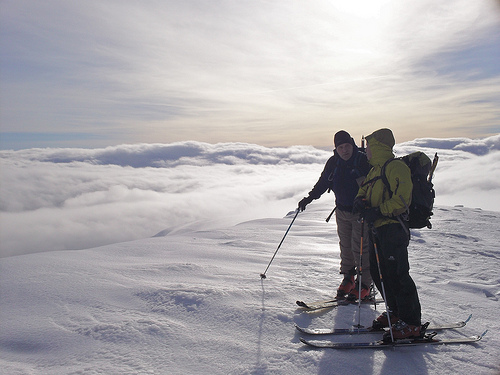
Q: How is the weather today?
A: It is cloudy.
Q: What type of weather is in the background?
A: It is cloudy.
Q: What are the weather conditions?
A: It is cloudy.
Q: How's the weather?
A: It is cloudy.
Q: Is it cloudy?
A: Yes, it is cloudy.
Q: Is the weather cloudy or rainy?
A: It is cloudy.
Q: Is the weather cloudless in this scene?
A: No, it is cloudy.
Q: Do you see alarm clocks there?
A: No, there are no alarm clocks.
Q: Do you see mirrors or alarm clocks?
A: No, there are no alarm clocks or mirrors.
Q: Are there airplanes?
A: No, there are no airplanes.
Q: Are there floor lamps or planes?
A: No, there are no planes or floor lamps.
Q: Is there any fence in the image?
A: No, there are no fences.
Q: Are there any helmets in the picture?
A: No, there are no helmets.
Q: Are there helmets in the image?
A: No, there are no helmets.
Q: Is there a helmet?
A: No, there are no helmets.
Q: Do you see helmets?
A: No, there are no helmets.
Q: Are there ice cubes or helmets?
A: No, there are no helmets or ice cubes.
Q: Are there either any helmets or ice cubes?
A: No, there are no helmets or ice cubes.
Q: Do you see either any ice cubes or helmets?
A: No, there are no helmets or ice cubes.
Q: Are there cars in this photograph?
A: No, there are no cars.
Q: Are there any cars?
A: No, there are no cars.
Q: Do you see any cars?
A: No, there are no cars.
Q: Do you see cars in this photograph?
A: No, there are no cars.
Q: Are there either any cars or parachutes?
A: No, there are no cars or parachutes.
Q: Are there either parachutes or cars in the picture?
A: No, there are no cars or parachutes.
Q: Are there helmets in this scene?
A: No, there are no helmets.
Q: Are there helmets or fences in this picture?
A: No, there are no helmets or fences.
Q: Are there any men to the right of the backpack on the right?
A: No, the man is to the left of the backpack.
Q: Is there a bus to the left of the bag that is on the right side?
A: No, there is a man to the left of the backpack.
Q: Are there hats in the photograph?
A: Yes, there is a hat.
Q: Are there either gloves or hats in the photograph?
A: Yes, there is a hat.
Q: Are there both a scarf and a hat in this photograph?
A: No, there is a hat but no scarves.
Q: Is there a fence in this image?
A: No, there are no fences.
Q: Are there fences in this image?
A: No, there are no fences.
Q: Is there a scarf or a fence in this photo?
A: No, there are no fences or scarves.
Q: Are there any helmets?
A: No, there are no helmets.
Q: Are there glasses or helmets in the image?
A: No, there are no helmets or glasses.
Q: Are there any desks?
A: No, there are no desks.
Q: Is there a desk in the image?
A: No, there are no desks.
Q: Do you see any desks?
A: No, there are no desks.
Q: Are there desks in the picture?
A: No, there are no desks.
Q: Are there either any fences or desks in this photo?
A: No, there are no desks or fences.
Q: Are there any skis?
A: Yes, there are skis.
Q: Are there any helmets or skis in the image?
A: Yes, there are skis.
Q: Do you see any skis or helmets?
A: Yes, there are skis.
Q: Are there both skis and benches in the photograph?
A: No, there are skis but no benches.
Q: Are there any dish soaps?
A: No, there are no dish soaps.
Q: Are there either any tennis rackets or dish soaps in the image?
A: No, there are no dish soaps or tennis rackets.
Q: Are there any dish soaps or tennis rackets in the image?
A: No, there are no dish soaps or tennis rackets.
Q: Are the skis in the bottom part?
A: Yes, the skis are in the bottom of the image.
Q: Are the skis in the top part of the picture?
A: No, the skis are in the bottom of the image.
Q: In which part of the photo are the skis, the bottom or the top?
A: The skis are in the bottom of the image.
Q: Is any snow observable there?
A: Yes, there is snow.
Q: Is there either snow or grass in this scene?
A: Yes, there is snow.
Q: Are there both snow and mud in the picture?
A: No, there is snow but no mud.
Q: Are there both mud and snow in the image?
A: No, there is snow but no mud.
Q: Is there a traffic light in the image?
A: No, there are no traffic lights.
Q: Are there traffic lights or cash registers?
A: No, there are no traffic lights or cash registers.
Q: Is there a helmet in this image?
A: No, there are no helmets.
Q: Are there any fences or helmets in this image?
A: No, there are no helmets or fences.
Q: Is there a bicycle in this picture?
A: No, there are no bicycles.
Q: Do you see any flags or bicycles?
A: No, there are no bicycles or flags.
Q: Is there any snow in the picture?
A: Yes, there is snow.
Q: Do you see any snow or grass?
A: Yes, there is snow.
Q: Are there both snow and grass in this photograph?
A: No, there is snow but no grass.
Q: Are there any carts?
A: No, there are no carts.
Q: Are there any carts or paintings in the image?
A: No, there are no carts or paintings.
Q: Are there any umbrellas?
A: No, there are no umbrellas.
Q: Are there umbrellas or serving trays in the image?
A: No, there are no umbrellas or serving trays.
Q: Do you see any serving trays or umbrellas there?
A: No, there are no umbrellas or serving trays.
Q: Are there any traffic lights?
A: No, there are no traffic lights.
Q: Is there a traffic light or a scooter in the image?
A: No, there are no traffic lights or scooters.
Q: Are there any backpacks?
A: Yes, there is a backpack.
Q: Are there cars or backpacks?
A: Yes, there is a backpack.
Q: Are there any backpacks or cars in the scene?
A: Yes, there is a backpack.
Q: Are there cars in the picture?
A: No, there are no cars.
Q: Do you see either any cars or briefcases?
A: No, there are no cars or briefcases.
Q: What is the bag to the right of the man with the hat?
A: The bag is a backpack.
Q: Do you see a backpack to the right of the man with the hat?
A: Yes, there is a backpack to the right of the man.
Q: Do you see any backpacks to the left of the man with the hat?
A: No, the backpack is to the right of the man.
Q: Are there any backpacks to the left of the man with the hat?
A: No, the backpack is to the right of the man.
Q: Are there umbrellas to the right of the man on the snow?
A: No, there is a backpack to the right of the man.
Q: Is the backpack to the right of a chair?
A: No, the backpack is to the right of the man.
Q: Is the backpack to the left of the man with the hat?
A: No, the backpack is to the right of the man.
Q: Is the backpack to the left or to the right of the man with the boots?
A: The backpack is to the right of the man.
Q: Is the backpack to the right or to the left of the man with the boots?
A: The backpack is to the right of the man.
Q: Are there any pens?
A: No, there are no pens.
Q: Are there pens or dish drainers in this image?
A: No, there are no pens or dish drainers.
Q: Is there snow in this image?
A: Yes, there is snow.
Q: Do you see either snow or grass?
A: Yes, there is snow.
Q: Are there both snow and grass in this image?
A: No, there is snow but no grass.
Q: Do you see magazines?
A: No, there are no magazines.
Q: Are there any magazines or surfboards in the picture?
A: No, there are no magazines or surfboards.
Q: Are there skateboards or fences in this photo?
A: No, there are no fences or skateboards.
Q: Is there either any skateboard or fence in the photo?
A: No, there are no fences or skateboards.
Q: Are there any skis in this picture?
A: Yes, there are skis.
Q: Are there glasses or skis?
A: Yes, there are skis.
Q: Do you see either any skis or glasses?
A: Yes, there are skis.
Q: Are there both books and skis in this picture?
A: No, there are skis but no books.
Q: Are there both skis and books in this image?
A: No, there are skis but no books.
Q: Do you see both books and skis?
A: No, there are skis but no books.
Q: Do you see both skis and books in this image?
A: No, there are skis but no books.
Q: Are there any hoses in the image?
A: No, there are no hoses.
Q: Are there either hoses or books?
A: No, there are no hoses or books.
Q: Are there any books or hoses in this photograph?
A: No, there are no hoses or books.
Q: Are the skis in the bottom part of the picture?
A: Yes, the skis are in the bottom of the image.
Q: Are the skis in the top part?
A: No, the skis are in the bottom of the image.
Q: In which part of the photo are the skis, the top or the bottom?
A: The skis are in the bottom of the image.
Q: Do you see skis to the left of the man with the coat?
A: Yes, there are skis to the left of the man.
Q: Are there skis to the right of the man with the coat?
A: No, the skis are to the left of the man.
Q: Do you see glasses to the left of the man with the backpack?
A: No, there are skis to the left of the man.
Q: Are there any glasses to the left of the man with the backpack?
A: No, there are skis to the left of the man.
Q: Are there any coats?
A: Yes, there is a coat.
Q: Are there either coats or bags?
A: Yes, there is a coat.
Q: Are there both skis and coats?
A: Yes, there are both a coat and skis.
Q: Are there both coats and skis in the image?
A: Yes, there are both a coat and skis.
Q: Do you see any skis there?
A: Yes, there are skis.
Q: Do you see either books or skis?
A: Yes, there are skis.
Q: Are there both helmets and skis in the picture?
A: No, there are skis but no helmets.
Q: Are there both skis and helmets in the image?
A: No, there are skis but no helmets.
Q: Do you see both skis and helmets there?
A: No, there are skis but no helmets.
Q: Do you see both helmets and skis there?
A: No, there are skis but no helmets.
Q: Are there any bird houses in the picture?
A: No, there are no bird houses.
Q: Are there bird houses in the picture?
A: No, there are no bird houses.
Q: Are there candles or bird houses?
A: No, there are no bird houses or candles.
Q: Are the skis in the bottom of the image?
A: Yes, the skis are in the bottom of the image.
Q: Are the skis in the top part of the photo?
A: No, the skis are in the bottom of the image.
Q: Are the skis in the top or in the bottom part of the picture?
A: The skis are in the bottom of the image.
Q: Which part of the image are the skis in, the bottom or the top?
A: The skis are in the bottom of the image.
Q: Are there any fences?
A: No, there are no fences.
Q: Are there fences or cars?
A: No, there are no fences or cars.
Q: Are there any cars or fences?
A: No, there are no fences or cars.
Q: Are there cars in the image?
A: No, there are no cars.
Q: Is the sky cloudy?
A: Yes, the sky is cloudy.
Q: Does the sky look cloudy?
A: Yes, the sky is cloudy.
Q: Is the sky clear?
A: No, the sky is cloudy.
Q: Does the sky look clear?
A: No, the sky is cloudy.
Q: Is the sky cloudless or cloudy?
A: The sky is cloudy.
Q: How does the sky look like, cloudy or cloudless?
A: The sky is cloudy.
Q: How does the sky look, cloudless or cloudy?
A: The sky is cloudy.